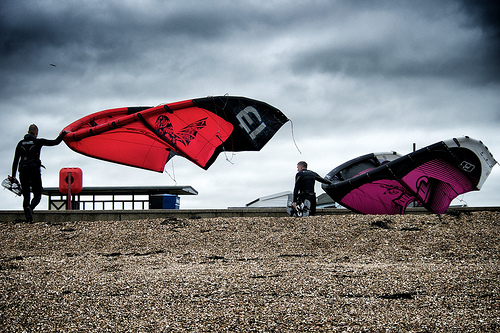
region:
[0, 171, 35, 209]
man holding packet in his hand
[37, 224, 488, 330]
rough tan and black pavement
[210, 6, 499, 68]
overcast skies with impending storm clouds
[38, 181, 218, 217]
long bench with steel partition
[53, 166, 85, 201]
orange container laying on bench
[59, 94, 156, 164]
red and black portion of large fabric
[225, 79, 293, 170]
black and white portion of flying object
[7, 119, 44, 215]
man wearing black long sleeve shirt and pants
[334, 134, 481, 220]
pink and black large object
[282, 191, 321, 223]
man carrying gray equipment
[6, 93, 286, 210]
Person holding something red.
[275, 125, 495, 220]
Person holding something purple.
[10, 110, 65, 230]
Person wearing a black outfit.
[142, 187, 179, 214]
Blue and black box.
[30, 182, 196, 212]
Building with a roof.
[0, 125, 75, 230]
Person wearing black shoes.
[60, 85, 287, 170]
Big red object in the air.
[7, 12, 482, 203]
Sky with dark gray clouds.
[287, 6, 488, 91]
Dark gray clouds.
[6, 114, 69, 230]
Person standing on the ground.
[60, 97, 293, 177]
a red and black wind glider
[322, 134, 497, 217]
a gray, purple and black wind glider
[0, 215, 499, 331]
sand and rock area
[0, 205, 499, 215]
a long wood planform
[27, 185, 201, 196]
a gray and white table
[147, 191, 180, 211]
a blue and white cooler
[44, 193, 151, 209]
a metal table support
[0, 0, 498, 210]
gray, white and blue sky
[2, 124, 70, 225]
a man wearing a sky driver uniform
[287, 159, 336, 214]
man wearing a black sky driver suit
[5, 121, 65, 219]
Man in a black wet suit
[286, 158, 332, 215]
man in a black wet suit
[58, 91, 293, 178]
Red wings with black tops and a black design with white letters E & I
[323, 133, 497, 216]
Pink Wings with black trim and white wing tips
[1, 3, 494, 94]
Cloudy and stormy dark gray clouds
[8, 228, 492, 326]
light brown gravel ground cover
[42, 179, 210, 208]
Brown and white roof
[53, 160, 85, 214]
Red square on a red post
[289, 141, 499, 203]
man in black wet suite holding pink wings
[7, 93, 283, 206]
man in black wet suite holding red wings